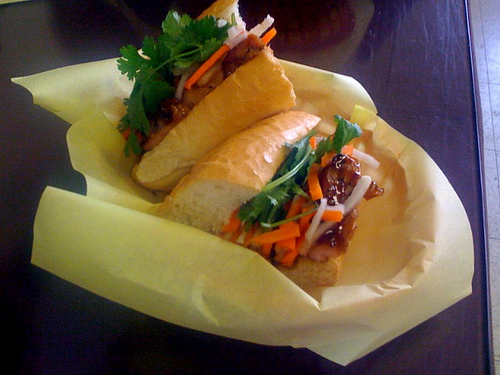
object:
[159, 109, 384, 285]
sandwich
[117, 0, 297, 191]
sandwich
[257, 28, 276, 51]
carrots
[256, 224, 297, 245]
carrots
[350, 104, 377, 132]
paper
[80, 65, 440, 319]
bowl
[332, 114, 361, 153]
greens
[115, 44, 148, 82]
greens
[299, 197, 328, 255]
onions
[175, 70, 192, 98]
onions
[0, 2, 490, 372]
table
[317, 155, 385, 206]
meat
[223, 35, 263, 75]
meat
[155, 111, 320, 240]
bread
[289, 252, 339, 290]
bread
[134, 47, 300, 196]
bread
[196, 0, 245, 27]
bread